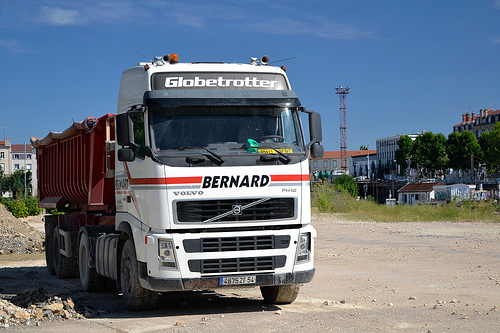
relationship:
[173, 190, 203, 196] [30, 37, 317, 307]
model name on truck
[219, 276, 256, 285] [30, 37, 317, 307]
license plate on truck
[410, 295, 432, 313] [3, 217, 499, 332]
rocks on ground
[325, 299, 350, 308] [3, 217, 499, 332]
rocks on ground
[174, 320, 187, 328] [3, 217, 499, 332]
rocks on ground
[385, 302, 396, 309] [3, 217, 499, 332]
rocks on ground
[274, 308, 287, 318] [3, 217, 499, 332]
rocks on ground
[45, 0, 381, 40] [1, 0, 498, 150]
clouds in sky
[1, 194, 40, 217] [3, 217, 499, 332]
bushes on ground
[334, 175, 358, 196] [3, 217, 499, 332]
bushes on ground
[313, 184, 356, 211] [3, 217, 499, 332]
bushes on ground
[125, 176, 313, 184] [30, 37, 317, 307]
stripe on truck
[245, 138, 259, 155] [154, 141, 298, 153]
hat on dashboard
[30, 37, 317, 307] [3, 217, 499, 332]
truck on ground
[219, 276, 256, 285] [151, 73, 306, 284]
license plate on front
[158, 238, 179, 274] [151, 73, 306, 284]
headlight on front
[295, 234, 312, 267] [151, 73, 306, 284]
headlight on front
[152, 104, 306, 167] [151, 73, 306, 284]
windshield on front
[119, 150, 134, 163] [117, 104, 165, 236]
mirror on side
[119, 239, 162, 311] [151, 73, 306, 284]
wheel on front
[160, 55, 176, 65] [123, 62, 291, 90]
horn on top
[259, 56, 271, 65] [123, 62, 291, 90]
horn on top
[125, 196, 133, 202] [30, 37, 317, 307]
tank on truck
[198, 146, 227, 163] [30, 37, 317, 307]
windshield wiper on truck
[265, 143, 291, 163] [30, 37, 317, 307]
windshield wiper on truck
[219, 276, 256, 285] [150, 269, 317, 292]
license plate on bumper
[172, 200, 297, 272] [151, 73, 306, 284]
grill on front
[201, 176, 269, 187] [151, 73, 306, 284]
bernard on front